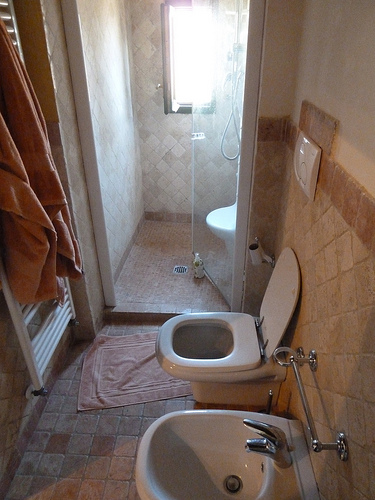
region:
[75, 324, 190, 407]
A towel is on the floor.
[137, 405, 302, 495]
A bidet.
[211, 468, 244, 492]
A drain.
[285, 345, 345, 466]
A metal bar attached to the wall.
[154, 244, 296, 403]
A toilet.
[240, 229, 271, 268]
An almost finished roll of toilet paper.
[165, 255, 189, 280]
A drain in the floor of the shower.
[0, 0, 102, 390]
A towel on a drying rack.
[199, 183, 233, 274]
A seat is inside the shower.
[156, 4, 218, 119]
A window.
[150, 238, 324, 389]
toilet with the seat up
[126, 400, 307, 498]
a white porcelain sink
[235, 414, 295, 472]
faucet on the sink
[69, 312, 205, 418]
towel in the floor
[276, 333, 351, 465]
towel rack on the wall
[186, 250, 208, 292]
bottle in the floor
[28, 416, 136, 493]
tiles in the floor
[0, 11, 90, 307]
towels hanging on the wall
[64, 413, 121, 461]
tiles of different colors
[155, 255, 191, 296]
drain of the shower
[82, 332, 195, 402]
pink towel on the floor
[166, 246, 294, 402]
white toilet with lid up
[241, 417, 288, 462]
silver metal sink faucet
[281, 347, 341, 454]
empty silver towel bar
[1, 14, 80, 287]
orange towels hanging up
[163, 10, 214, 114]
window in tile wall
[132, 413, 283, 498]
white oval sink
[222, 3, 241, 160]
silver shower faucet and cord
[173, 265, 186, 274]
shower drain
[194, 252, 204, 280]
bottle on shower floor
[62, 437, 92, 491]
the floor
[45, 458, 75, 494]
the floor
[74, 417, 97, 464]
the floor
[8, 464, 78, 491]
the floor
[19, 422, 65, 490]
the floor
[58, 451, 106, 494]
the floor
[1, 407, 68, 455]
the floor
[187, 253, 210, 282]
The bottle is in the shower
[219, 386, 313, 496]
The faucet is metal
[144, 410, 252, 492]
the sink is empty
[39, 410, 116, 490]
The floor is light colored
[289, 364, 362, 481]
The bar is metal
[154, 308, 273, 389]
The toilet seat is up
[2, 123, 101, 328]
The towel is hanging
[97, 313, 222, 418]
The towel is on the floor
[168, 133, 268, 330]
The shower door is open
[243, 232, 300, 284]
The toilet paper is gone